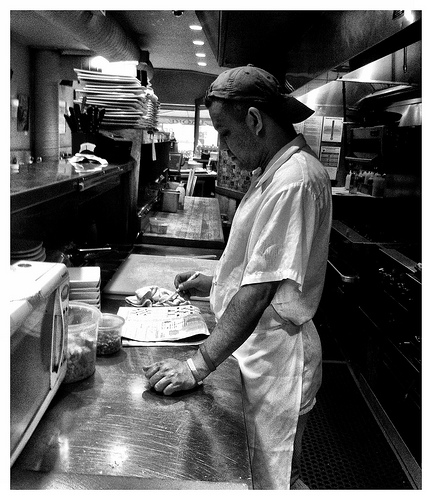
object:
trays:
[75, 61, 162, 136]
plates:
[72, 68, 161, 132]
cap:
[205, 63, 316, 123]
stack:
[74, 67, 158, 131]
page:
[119, 303, 207, 346]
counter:
[11, 184, 254, 488]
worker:
[142, 63, 332, 492]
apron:
[214, 322, 304, 490]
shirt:
[210, 133, 332, 419]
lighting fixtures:
[189, 24, 207, 66]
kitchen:
[8, 10, 420, 490]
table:
[142, 197, 224, 242]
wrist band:
[198, 343, 215, 372]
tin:
[159, 190, 181, 213]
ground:
[239, 316, 421, 492]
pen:
[167, 271, 200, 300]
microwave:
[10, 260, 69, 470]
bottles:
[345, 169, 415, 197]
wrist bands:
[185, 358, 203, 385]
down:
[9, 247, 422, 490]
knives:
[63, 97, 105, 132]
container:
[72, 133, 133, 161]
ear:
[248, 106, 263, 136]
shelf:
[9, 151, 138, 199]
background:
[10, 10, 429, 196]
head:
[205, 64, 293, 172]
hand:
[143, 357, 198, 395]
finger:
[143, 359, 175, 395]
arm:
[187, 182, 311, 380]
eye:
[221, 127, 232, 138]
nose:
[217, 132, 229, 151]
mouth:
[228, 155, 238, 162]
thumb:
[179, 278, 200, 291]